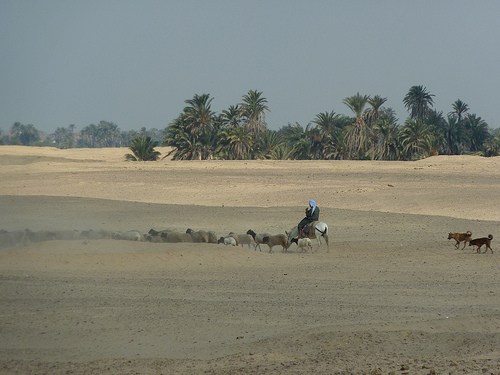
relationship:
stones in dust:
[379, 360, 500, 374] [29, 213, 486, 374]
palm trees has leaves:
[0, 89, 499, 169] [188, 93, 213, 117]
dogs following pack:
[448, 229, 496, 256] [144, 217, 499, 265]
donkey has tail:
[286, 215, 331, 251] [316, 223, 328, 239]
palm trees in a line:
[0, 89, 499, 169] [4, 85, 499, 158]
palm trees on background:
[0, 89, 499, 169] [4, 94, 496, 161]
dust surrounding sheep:
[122, 223, 282, 250] [124, 226, 291, 251]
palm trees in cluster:
[0, 89, 499, 169] [137, 72, 497, 172]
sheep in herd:
[124, 226, 291, 251] [144, 215, 296, 253]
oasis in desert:
[1, 194, 499, 370] [4, 5, 498, 375]